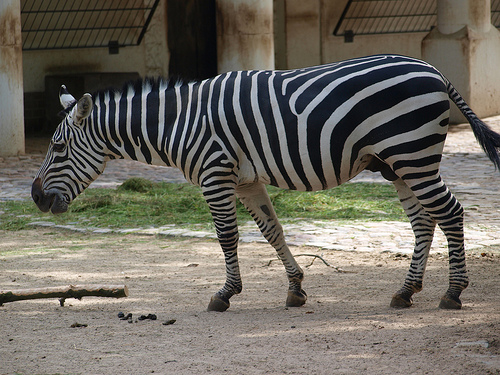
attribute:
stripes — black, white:
[173, 83, 334, 162]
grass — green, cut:
[92, 193, 199, 225]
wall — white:
[0, 0, 496, 116]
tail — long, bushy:
[422, 53, 500, 176]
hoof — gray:
[203, 292, 238, 316]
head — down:
[11, 78, 120, 209]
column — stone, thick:
[210, 1, 286, 100]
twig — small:
[265, 251, 348, 285]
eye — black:
[49, 141, 73, 162]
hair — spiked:
[71, 71, 208, 109]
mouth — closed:
[19, 176, 83, 217]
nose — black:
[24, 182, 54, 214]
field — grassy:
[1, 95, 500, 242]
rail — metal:
[6, 0, 171, 56]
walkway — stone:
[1, 95, 278, 203]